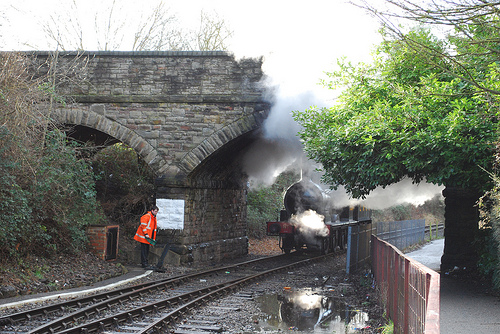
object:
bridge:
[1, 45, 498, 270]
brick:
[128, 108, 142, 118]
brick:
[242, 73, 254, 77]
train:
[263, 159, 375, 256]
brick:
[205, 134, 221, 149]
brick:
[170, 107, 186, 112]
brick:
[129, 109, 141, 118]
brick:
[119, 63, 128, 68]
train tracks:
[0, 221, 446, 333]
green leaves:
[367, 136, 374, 141]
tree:
[289, 19, 499, 260]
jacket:
[134, 212, 159, 246]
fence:
[371, 232, 443, 333]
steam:
[284, 207, 329, 241]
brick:
[192, 146, 208, 161]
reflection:
[311, 296, 353, 331]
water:
[253, 284, 376, 333]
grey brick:
[172, 150, 190, 164]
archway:
[39, 119, 153, 274]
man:
[130, 202, 163, 272]